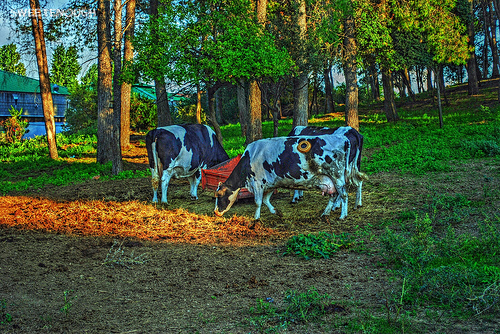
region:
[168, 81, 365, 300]
The cows are visible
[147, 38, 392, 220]
The cows are visible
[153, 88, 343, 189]
The cows are visible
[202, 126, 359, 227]
a black and white cow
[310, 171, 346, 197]
an udder on a cow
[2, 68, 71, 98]
a green roof on a house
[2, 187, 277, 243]
light shining onto the ground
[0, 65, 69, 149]
a building in the background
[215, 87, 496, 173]
grass under the trees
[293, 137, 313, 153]
a circular object on a cow's side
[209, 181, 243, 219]
a cow head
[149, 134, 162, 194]
a dirty cow tail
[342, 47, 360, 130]
a brown tree trunk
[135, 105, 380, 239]
Three cows in a forest chewing the grass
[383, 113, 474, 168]
Thick green grass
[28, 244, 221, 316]
Patchy brown grass in shadows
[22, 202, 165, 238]
Grass that looks golden in the light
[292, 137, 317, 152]
Golden raised circle on the side of a cow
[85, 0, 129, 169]
Tall brown tree trunk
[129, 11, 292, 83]
Green leaves of a tree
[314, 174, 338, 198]
White and pink cow's udder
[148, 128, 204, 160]
Black and white coloring on the side of a cow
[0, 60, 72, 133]
Blue and green building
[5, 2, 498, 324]
cows are eating grass on a hillside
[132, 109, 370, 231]
the cows are black and white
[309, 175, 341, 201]
the cow has an udder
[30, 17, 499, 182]
trees are behind the cows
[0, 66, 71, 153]
a building is near the cows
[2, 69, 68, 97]
the building has a green roof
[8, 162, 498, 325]
brown patches are in the field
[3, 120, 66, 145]
a cement wall is under the house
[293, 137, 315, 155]
a brown circle is on the side of the cow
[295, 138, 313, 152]
the brown circle has a hole in the center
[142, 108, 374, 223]
three cows are grazing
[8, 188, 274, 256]
light shining on dirt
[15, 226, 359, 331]
dirt is dark brown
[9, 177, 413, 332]
ground is bare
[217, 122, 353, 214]
cow is black and white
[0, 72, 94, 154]
building in left background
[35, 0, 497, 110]
forest behind three cows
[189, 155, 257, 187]
red trough between cows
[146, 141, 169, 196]
cows have white tails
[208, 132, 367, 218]
cow has head bent down